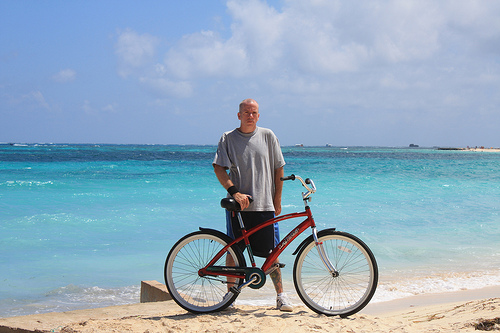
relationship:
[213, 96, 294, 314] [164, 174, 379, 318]
man has a bike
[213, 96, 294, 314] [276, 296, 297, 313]
man has shoe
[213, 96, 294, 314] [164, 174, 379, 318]
man has bike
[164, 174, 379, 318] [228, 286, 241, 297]
bike has pedal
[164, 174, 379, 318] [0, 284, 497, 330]
bike on beach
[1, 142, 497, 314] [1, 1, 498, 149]
ocean meets sky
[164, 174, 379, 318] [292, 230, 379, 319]
bike has wheel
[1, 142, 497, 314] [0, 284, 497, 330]
ocean meets beach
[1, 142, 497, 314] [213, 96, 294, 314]
ocean behind man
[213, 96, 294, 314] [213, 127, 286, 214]
man wearing shirt